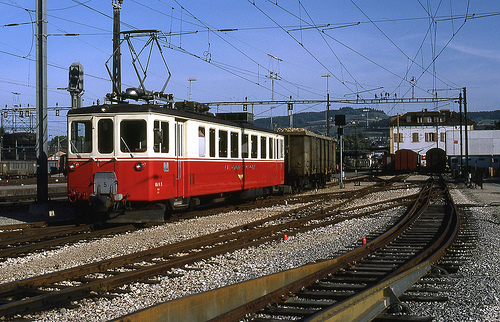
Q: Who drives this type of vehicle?
A: Conductor.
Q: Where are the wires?
A: Above the train.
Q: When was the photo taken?
A: Daytime.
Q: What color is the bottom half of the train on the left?
A: Red.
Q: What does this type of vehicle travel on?
A: Tracks.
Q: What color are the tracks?
A: Brown.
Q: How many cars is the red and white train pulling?
A: One.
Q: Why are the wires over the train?
A: For electricity.